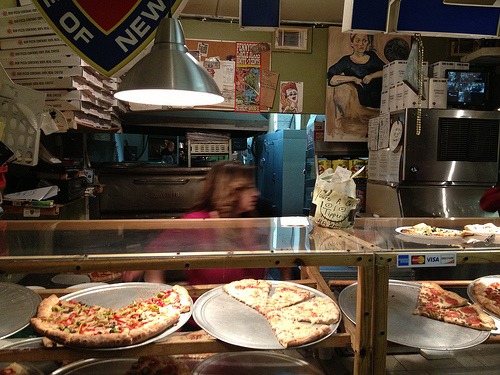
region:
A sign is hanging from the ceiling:
[32, 8, 303, 99]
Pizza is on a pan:
[18, 290, 355, 357]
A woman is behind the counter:
[169, 171, 359, 296]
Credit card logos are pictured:
[388, 245, 498, 270]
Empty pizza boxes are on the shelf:
[6, 48, 176, 164]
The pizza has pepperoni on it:
[400, 278, 470, 363]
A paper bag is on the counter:
[287, 150, 410, 237]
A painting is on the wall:
[317, 29, 495, 194]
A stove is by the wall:
[380, 96, 495, 215]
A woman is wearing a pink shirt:
[155, 205, 298, 287]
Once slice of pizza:
[260, 314, 330, 351]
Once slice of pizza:
[267, 301, 344, 319]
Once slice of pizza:
[209, 271, 270, 322]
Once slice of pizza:
[268, 266, 308, 328]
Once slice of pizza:
[408, 277, 495, 344]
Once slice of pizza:
[27, 293, 189, 363]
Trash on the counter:
[304, 145, 369, 238]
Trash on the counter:
[385, 206, 498, 248]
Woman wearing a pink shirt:
[131, 150, 293, 347]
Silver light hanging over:
[98, 1, 231, 135]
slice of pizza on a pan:
[273, 315, 323, 348]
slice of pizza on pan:
[291, 295, 337, 326]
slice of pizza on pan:
[270, 278, 320, 308]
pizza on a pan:
[221, 265, 266, 316]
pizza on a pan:
[440, 303, 492, 333]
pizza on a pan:
[43, 273, 188, 351]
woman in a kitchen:
[185, 150, 266, 210]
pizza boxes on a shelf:
[61, 70, 106, 138]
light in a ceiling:
[113, 28, 220, 104]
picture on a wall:
[317, 34, 372, 141]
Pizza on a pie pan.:
[21, 272, 183, 352]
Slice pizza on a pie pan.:
[22, 263, 197, 360]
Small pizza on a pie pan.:
[28, 265, 192, 354]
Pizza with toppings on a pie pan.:
[28, 267, 194, 359]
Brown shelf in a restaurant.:
[12, 201, 493, 266]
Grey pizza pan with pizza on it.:
[187, 268, 352, 355]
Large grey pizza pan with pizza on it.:
[187, 261, 339, 358]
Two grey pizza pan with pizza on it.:
[32, 270, 339, 361]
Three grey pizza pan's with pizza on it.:
[27, 265, 488, 361]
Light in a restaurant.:
[110, 8, 240, 142]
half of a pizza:
[223, 280, 336, 347]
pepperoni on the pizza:
[447, 309, 460, 320]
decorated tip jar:
[313, 168, 356, 230]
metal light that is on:
[115, 17, 222, 109]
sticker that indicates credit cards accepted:
[395, 252, 457, 267]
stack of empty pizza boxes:
[3, 4, 115, 128]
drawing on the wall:
[278, 80, 303, 113]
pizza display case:
[34, 280, 499, 347]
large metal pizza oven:
[370, 108, 497, 216]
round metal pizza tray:
[196, 279, 333, 351]